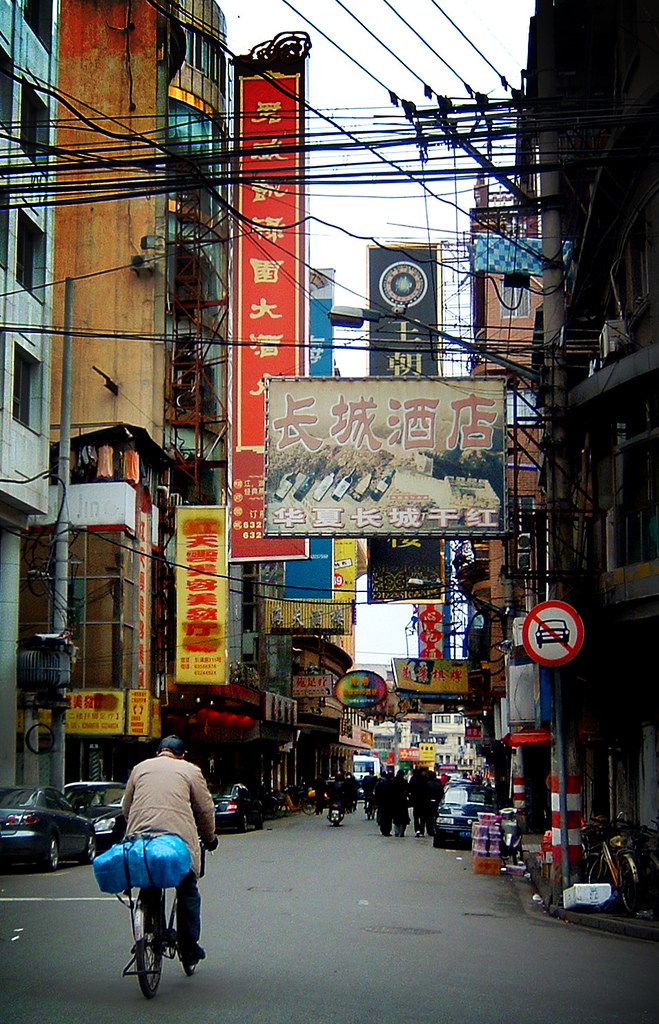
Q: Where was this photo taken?
A: In a metropolitan area.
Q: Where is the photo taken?
A: On a road.